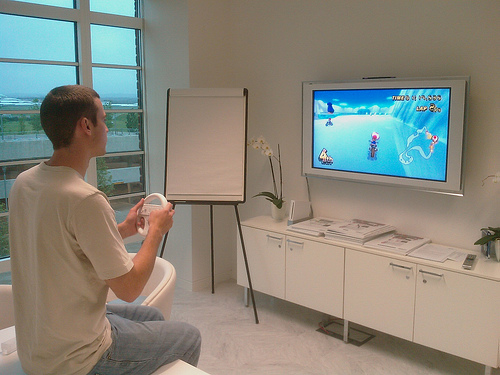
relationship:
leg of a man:
[127, 321, 208, 368] [8, 82, 206, 375]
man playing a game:
[8, 82, 206, 375] [312, 91, 448, 177]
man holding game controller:
[8, 82, 206, 375] [134, 194, 176, 233]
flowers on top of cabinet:
[248, 127, 283, 208] [233, 216, 499, 374]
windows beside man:
[1, 3, 153, 272] [8, 82, 206, 375]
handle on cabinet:
[267, 229, 282, 243] [233, 216, 499, 374]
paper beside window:
[159, 84, 250, 202] [90, 27, 146, 237]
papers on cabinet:
[293, 211, 456, 270] [233, 216, 499, 374]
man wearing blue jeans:
[8, 82, 206, 375] [104, 303, 202, 371]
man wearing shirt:
[8, 82, 206, 375] [8, 162, 134, 374]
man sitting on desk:
[8, 82, 206, 375] [0, 318, 209, 372]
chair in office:
[107, 251, 176, 324] [2, 0, 499, 373]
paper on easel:
[159, 84, 250, 202] [150, 86, 267, 328]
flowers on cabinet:
[248, 127, 283, 208] [233, 216, 499, 374]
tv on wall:
[302, 78, 467, 195] [189, 4, 499, 327]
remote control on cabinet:
[460, 251, 476, 271] [233, 216, 499, 374]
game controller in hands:
[134, 194, 176, 233] [128, 196, 177, 240]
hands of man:
[128, 196, 177, 240] [8, 82, 206, 375]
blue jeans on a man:
[104, 303, 202, 371] [8, 82, 206, 375]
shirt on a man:
[8, 162, 134, 374] [8, 82, 206, 375]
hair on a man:
[38, 83, 103, 146] [8, 82, 206, 375]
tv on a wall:
[302, 78, 467, 195] [189, 4, 499, 327]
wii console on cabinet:
[287, 196, 309, 222] [233, 216, 499, 374]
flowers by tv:
[248, 127, 283, 208] [302, 78, 467, 195]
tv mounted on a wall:
[302, 78, 467, 195] [189, 4, 499, 327]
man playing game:
[8, 82, 206, 375] [312, 91, 448, 177]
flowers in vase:
[248, 127, 283, 208] [271, 203, 286, 223]